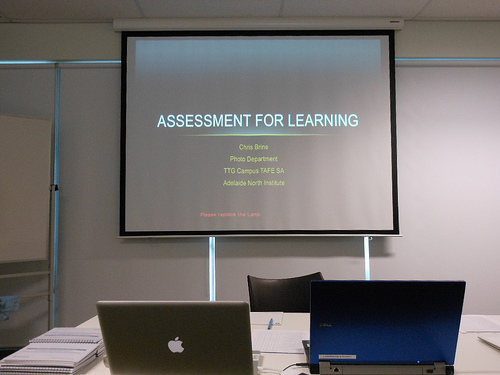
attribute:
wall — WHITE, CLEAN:
[0, 22, 499, 345]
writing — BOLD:
[156, 112, 358, 127]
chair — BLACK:
[247, 271, 322, 312]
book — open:
[0, 331, 107, 375]